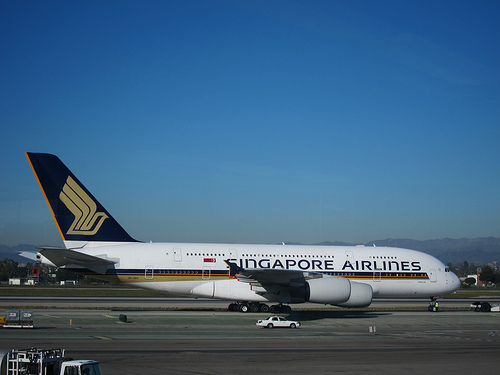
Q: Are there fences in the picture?
A: No, there are no fences.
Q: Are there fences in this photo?
A: No, there are no fences.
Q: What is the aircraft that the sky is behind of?
A: The aircraft is an airplane.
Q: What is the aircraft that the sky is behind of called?
A: The aircraft is an airplane.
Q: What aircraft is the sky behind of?
A: The sky is behind the airplane.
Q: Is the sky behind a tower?
A: No, the sky is behind the plane.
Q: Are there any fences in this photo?
A: No, there are no fences.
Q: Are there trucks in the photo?
A: Yes, there is a truck.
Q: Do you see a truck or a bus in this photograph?
A: Yes, there is a truck.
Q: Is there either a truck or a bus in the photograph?
A: Yes, there is a truck.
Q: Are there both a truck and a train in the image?
A: No, there is a truck but no trains.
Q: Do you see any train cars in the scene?
A: No, there are no train cars.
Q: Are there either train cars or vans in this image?
A: No, there are no train cars or vans.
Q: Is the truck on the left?
A: Yes, the truck is on the left of the image.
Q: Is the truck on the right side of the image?
A: No, the truck is on the left of the image.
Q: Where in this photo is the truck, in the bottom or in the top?
A: The truck is in the bottom of the image.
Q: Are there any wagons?
A: No, there are no wagons.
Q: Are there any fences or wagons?
A: No, there are no wagons or fences.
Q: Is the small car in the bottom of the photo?
A: Yes, the car is in the bottom of the image.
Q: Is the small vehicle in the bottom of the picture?
A: Yes, the car is in the bottom of the image.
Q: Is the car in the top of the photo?
A: No, the car is in the bottom of the image.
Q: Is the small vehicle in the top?
A: No, the car is in the bottom of the image.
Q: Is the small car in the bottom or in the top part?
A: The car is in the bottom of the image.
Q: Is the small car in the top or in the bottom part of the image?
A: The car is in the bottom of the image.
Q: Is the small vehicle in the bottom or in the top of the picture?
A: The car is in the bottom of the image.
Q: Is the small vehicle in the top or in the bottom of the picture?
A: The car is in the bottom of the image.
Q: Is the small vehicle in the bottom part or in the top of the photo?
A: The car is in the bottom of the image.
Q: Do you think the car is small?
A: Yes, the car is small.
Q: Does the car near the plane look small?
A: Yes, the car is small.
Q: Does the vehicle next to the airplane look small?
A: Yes, the car is small.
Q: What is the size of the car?
A: The car is small.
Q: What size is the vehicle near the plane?
A: The car is small.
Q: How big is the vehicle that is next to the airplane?
A: The car is small.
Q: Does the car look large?
A: No, the car is small.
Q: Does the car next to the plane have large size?
A: No, the car is small.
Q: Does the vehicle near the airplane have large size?
A: No, the car is small.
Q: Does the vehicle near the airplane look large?
A: No, the car is small.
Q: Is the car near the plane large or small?
A: The car is small.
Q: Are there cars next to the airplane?
A: Yes, there is a car next to the airplane.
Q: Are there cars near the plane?
A: Yes, there is a car near the plane.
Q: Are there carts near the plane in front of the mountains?
A: No, there is a car near the plane.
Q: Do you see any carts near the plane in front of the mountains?
A: No, there is a car near the plane.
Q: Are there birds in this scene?
A: No, there are no birds.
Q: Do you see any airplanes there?
A: Yes, there is an airplane.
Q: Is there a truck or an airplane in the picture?
A: Yes, there is an airplane.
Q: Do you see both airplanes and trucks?
A: Yes, there are both an airplane and a truck.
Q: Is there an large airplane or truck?
A: Yes, there is a large airplane.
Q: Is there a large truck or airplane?
A: Yes, there is a large airplane.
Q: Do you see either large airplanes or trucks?
A: Yes, there is a large airplane.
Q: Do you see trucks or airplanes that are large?
A: Yes, the airplane is large.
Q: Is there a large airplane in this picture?
A: Yes, there is a large airplane.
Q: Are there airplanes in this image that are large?
A: Yes, there is an airplane that is large.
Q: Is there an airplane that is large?
A: Yes, there is an airplane that is large.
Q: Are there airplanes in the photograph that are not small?
A: Yes, there is a large airplane.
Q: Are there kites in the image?
A: No, there are no kites.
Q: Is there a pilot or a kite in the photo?
A: No, there are no kites or pilots.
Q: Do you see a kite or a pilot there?
A: No, there are no kites or pilots.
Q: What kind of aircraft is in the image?
A: The aircraft is an airplane.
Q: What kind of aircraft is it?
A: The aircraft is an airplane.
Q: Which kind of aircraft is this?
A: That is an airplane.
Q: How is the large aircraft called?
A: The aircraft is an airplane.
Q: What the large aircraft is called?
A: The aircraft is an airplane.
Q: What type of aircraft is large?
A: The aircraft is an airplane.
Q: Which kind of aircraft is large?
A: The aircraft is an airplane.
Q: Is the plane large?
A: Yes, the plane is large.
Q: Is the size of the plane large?
A: Yes, the plane is large.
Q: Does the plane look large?
A: Yes, the plane is large.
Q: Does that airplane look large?
A: Yes, the airplane is large.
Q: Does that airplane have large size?
A: Yes, the airplane is large.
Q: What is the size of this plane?
A: The plane is large.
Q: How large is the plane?
A: The plane is large.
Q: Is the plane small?
A: No, the plane is large.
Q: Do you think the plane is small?
A: No, the plane is large.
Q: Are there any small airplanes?
A: No, there is an airplane but it is large.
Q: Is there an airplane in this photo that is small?
A: No, there is an airplane but it is large.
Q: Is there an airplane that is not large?
A: No, there is an airplane but it is large.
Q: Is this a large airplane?
A: Yes, this is a large airplane.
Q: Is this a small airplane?
A: No, this is a large airplane.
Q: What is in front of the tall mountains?
A: The airplane is in front of the mountains.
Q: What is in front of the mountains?
A: The airplane is in front of the mountains.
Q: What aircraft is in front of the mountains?
A: The aircraft is an airplane.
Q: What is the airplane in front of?
A: The airplane is in front of the mountains.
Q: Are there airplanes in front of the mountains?
A: Yes, there is an airplane in front of the mountains.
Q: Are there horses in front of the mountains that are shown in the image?
A: No, there is an airplane in front of the mountains.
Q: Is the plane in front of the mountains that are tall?
A: Yes, the plane is in front of the mountains.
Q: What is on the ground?
A: The airplane is on the ground.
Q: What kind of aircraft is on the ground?
A: The aircraft is an airplane.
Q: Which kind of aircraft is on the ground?
A: The aircraft is an airplane.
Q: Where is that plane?
A: The plane is on the ground.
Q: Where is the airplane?
A: The plane is on the ground.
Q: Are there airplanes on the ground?
A: Yes, there is an airplane on the ground.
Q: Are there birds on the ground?
A: No, there is an airplane on the ground.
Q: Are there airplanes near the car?
A: Yes, there is an airplane near the car.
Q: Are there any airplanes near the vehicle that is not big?
A: Yes, there is an airplane near the car.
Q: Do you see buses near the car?
A: No, there is an airplane near the car.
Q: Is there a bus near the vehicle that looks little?
A: No, there is an airplane near the car.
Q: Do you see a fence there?
A: No, there are no fences.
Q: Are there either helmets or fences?
A: No, there are no fences or helmets.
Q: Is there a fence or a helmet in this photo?
A: No, there are no fences or helmets.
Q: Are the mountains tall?
A: Yes, the mountains are tall.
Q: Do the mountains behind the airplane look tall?
A: Yes, the mountains are tall.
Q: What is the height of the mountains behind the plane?
A: The mountains are tall.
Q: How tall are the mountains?
A: The mountains are tall.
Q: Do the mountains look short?
A: No, the mountains are tall.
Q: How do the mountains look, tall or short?
A: The mountains are tall.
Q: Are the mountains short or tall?
A: The mountains are tall.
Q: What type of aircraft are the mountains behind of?
A: The mountains are behind the airplane.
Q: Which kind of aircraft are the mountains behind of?
A: The mountains are behind the airplane.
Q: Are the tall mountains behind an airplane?
A: Yes, the mountains are behind an airplane.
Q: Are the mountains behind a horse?
A: No, the mountains are behind an airplane.